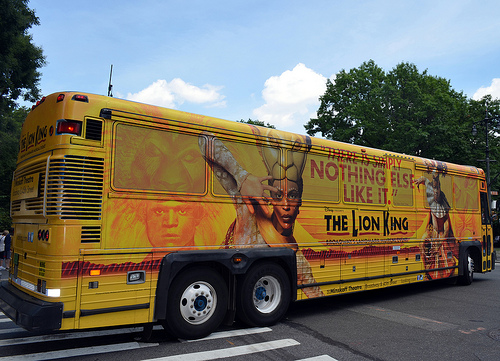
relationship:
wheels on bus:
[168, 259, 291, 319] [15, 93, 497, 278]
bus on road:
[15, 93, 497, 278] [347, 322, 484, 346]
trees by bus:
[325, 70, 476, 144] [15, 93, 497, 278]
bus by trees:
[15, 93, 497, 278] [325, 70, 476, 144]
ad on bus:
[301, 135, 427, 246] [15, 93, 497, 278]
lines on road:
[208, 346, 312, 361] [347, 322, 484, 346]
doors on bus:
[469, 183, 494, 272] [15, 93, 497, 278]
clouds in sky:
[136, 76, 342, 123] [52, 7, 492, 125]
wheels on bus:
[158, 259, 297, 330] [15, 93, 497, 278]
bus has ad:
[15, 93, 497, 278] [301, 135, 427, 246]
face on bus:
[251, 171, 310, 226] [15, 93, 497, 278]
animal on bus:
[410, 150, 462, 285] [15, 93, 497, 278]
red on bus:
[303, 140, 416, 202] [15, 93, 497, 278]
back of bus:
[1, 285, 62, 333] [15, 93, 497, 278]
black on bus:
[319, 208, 412, 241] [15, 93, 497, 278]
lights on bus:
[51, 114, 82, 135] [15, 93, 497, 278]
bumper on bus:
[1, 285, 62, 333] [15, 93, 497, 278]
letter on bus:
[332, 214, 346, 234] [15, 93, 497, 278]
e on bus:
[342, 211, 348, 233] [15, 93, 497, 278]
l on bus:
[348, 209, 362, 238] [15, 93, 497, 278]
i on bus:
[357, 216, 365, 239] [15, 93, 497, 278]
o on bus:
[362, 213, 372, 238] [15, 93, 497, 278]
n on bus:
[367, 216, 382, 233] [15, 93, 497, 278]